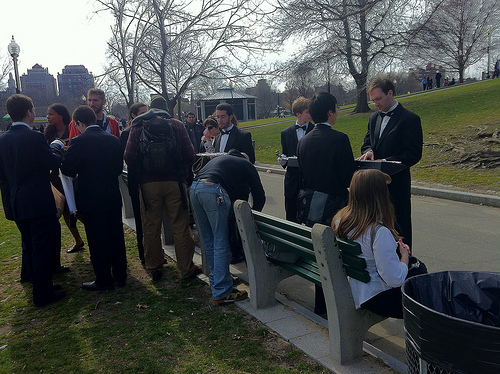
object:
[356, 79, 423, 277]
man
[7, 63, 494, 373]
park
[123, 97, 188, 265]
man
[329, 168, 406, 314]
woman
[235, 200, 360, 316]
bench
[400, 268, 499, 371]
trash can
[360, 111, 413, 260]
suit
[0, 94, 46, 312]
man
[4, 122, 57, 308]
suit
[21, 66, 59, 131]
buiding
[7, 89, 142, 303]
people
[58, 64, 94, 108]
buiding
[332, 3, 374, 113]
tree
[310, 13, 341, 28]
leaves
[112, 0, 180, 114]
tree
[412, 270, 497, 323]
bag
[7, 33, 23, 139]
light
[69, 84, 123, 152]
man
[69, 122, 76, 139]
red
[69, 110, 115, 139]
jacket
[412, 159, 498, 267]
road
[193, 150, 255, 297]
man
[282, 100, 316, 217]
boy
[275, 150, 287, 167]
bell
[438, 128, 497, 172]
roots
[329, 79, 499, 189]
ground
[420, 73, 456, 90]
people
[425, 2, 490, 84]
tree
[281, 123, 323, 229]
suit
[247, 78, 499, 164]
grass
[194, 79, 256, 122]
buiding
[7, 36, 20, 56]
light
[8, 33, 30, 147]
pole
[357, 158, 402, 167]
tray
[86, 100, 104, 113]
beard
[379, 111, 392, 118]
tie